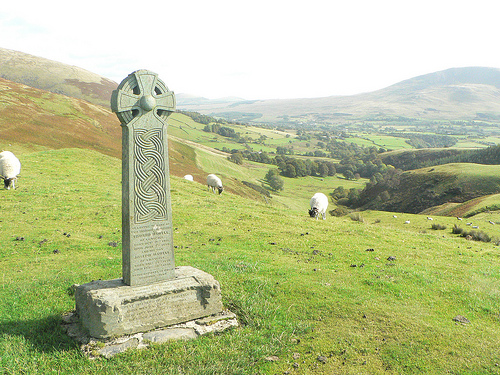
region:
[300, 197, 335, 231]
white sheep in field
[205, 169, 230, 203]
white sheep in field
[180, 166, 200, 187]
white sheep in field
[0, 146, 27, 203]
white sheep in field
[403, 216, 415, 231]
white sheep in field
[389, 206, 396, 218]
white sheep in field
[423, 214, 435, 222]
white sheep in field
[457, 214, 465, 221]
white sheep in field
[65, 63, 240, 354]
celtic cross on tombstone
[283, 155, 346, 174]
mass of green trees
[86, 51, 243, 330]
an epitaph on the hill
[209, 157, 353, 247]
the sheep are eating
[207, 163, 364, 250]
the sheep are eating grass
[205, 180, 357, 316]
the grass on the ground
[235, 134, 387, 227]
trees at the foot of the hill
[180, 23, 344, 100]
the sky is clear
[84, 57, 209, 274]
the epitaph is gray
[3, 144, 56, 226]
the sheep's fur is white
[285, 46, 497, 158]
taller hills in the distance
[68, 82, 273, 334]
the epitaph has cross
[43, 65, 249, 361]
A gray stone monument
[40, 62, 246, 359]
Writing on the monument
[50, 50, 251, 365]
Celtic symbols on the monument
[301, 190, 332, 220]
The sheep is grazing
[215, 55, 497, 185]
Several hills in the distance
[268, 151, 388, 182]
A cluster of trees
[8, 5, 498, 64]
The sky is cloudy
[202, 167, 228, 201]
A white sheep eating grass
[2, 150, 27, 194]
The sheep's head is black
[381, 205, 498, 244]
More sheep off in the distance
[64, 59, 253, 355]
a stone marker in a field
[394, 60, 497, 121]
a hill in the distance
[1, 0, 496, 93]
a pale grey sky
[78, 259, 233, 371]
the concrete base of a marker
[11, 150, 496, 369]
a green grassy field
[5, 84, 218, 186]
a brown dirt field on a hillside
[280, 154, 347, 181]
trees in a valley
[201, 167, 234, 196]
a sheep grazing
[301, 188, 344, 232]
a white sheep with a black face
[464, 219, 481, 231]
sheep laying down in a field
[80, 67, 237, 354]
a celtic cross stone monument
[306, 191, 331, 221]
a black and white sheep grazing on a hill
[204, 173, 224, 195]
a black and white sheep grazing on a hill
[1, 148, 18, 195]
a black and white sheep grazing on a hill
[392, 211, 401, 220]
a black and white sheep grazing on a hill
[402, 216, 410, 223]
a black and white sheep grazing on a hill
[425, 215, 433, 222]
a black and white sheep grazing on a hill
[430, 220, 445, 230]
a green bush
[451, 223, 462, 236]
a green bush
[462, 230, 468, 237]
a green bush